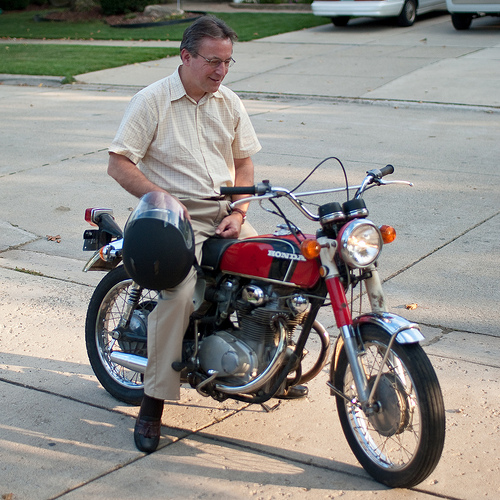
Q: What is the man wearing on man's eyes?
A: Eyeglasses.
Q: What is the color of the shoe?
A: Black.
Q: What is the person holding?
A: A helmet.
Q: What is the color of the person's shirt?
A: Yellow.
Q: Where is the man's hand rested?
A: On the seat of the bike.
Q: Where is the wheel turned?
A: Right.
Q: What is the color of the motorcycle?
A: Red.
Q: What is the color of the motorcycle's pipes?
A: Silver.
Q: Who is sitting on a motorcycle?
A: A man.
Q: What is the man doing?
A: Sitting on a motorcycle.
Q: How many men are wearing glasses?
A: One.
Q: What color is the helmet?
A: Black.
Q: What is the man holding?
A: A helmet.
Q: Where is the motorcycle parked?
A: On a driveway.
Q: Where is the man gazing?
A: Down at the motorcycle.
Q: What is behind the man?
A: Street.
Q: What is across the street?
A: A driveway.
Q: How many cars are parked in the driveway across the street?
A: Two.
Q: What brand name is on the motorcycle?
A: Honda.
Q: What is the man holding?
A: Helmet.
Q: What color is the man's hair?
A: Black.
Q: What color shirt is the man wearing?
A: Yellow.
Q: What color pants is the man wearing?
A: Khaki.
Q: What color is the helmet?
A: Black.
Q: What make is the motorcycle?
A: Honda.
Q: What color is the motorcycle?
A: Red and Black.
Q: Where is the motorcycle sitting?
A: Driveway.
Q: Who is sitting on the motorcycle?
A: Older man.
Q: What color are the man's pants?
A: Tan.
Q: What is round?
A: Tires.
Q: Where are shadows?
A: On the ground.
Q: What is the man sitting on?
A: A motorcycle.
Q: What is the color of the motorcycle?
A: Red.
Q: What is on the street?
A: Nothing is on the street.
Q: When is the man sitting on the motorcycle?
A: Now.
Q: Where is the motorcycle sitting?
A: On the side of the street.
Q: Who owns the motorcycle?
A: The man.